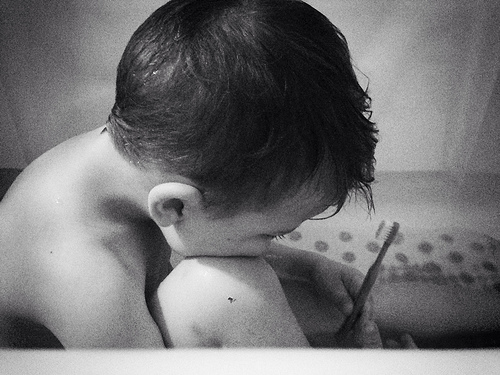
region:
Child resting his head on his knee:
[0, 0, 439, 366]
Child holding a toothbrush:
[12, 0, 409, 351]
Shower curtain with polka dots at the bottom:
[346, 67, 497, 304]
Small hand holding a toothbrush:
[303, 204, 402, 354]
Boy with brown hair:
[89, 0, 386, 284]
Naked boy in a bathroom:
[1, 0, 376, 341]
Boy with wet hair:
[7, 5, 397, 340]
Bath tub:
[391, 141, 493, 343]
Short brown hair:
[101, 0, 389, 241]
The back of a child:
[3, 75, 188, 350]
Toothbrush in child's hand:
[373, 220, 405, 296]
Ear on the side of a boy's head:
[131, 177, 209, 224]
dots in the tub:
[417, 217, 483, 290]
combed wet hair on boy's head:
[322, 106, 398, 202]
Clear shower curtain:
[405, 12, 493, 175]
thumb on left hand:
[321, 272, 358, 318]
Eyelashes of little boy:
[264, 228, 295, 241]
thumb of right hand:
[357, 320, 385, 344]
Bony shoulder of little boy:
[60, 210, 145, 282]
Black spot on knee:
[201, 287, 262, 314]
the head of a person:
[98, 0, 381, 266]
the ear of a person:
[141, 173, 211, 230]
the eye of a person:
[258, 222, 298, 248]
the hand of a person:
[311, 241, 379, 325]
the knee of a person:
[173, 236, 279, 294]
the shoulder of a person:
[43, 249, 149, 351]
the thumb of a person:
[318, 270, 357, 317]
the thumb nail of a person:
[341, 299, 354, 315]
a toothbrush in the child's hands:
[328, 215, 403, 344]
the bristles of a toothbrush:
[371, 215, 401, 248]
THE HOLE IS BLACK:
[419, 256, 441, 263]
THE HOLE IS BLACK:
[411, 241, 431, 268]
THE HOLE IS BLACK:
[430, 230, 441, 285]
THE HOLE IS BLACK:
[416, 238, 436, 259]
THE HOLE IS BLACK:
[422, 254, 437, 290]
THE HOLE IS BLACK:
[423, 247, 440, 270]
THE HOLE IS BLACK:
[424, 256, 443, 269]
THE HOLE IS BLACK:
[408, 258, 430, 284]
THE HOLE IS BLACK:
[432, 261, 447, 281]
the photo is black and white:
[28, 13, 475, 324]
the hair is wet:
[253, 91, 412, 253]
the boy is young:
[38, 74, 448, 334]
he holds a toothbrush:
[336, 205, 448, 338]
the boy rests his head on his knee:
[101, 144, 337, 329]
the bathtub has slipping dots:
[368, 147, 466, 292]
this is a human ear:
[116, 152, 261, 277]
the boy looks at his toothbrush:
[234, 200, 468, 367]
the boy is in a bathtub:
[9, 94, 478, 374]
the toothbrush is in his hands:
[27, 84, 444, 322]